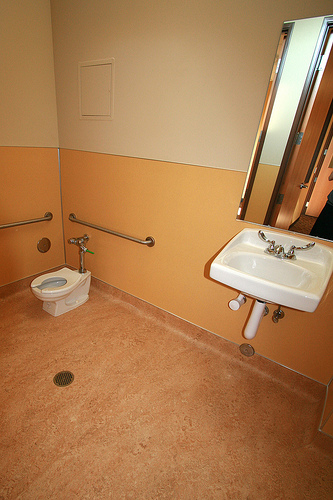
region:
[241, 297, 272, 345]
a white pipe under a sink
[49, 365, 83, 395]
a drain in a concrete floor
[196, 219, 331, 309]
a white bathroom sink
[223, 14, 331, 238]
a mirror over a sink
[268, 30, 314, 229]
a door reflected in a mirror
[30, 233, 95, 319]
a short white toilet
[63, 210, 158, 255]
metal railing around a toilet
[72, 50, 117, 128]
a small door in the wall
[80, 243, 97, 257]
a green flush lever on a toilet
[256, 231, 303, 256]
a faucet on a sink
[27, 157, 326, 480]
a clean public bathroom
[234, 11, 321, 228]
a shiny bathroom mirror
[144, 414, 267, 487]
the tan bathroom floor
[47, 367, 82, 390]
a drain in the floor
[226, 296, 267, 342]
white pipes under the sink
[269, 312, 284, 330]
water cut off valve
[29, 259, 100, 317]
a white bathroom toilet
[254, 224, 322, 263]
shiny silver faucet handles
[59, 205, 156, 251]
the handicap railing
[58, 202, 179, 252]
METAL BAR ON BATHROOM WALL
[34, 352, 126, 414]
DRAIN HOLE IN BATHROOM FLOOR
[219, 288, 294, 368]
PLUMBING PIPES TO THE BATHROOM SINK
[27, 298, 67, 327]
BROWN BATHROOM FLOORING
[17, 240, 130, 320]
WHITE TOILET IN A BATHROOM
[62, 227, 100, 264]
GREEN FLUSHING HANDLE ON TOILET PLUMBING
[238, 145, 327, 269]
MIRROR IN A BATHROOM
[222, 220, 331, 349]
WHITE SINK ATTACHED TO BATHROOM WALL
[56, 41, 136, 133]
SQUARE ACCESS PANEL IN BATHROOM WALL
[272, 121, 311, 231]
DOOR HINGES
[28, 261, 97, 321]
short white toilet fixture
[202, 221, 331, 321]
white porcelain sink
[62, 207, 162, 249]
metal silver safety bar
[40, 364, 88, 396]
brassy floor drain for water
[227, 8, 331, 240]
big mirror in front of sink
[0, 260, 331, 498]
burnt sienna colored linoleum flooring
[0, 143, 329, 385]
light orange coloured wainscotting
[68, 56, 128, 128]
small door in the wall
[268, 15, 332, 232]
reflection of a wooden door with a metal fram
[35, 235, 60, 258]
silver disk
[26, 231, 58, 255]
round silver orb on wall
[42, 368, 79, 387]
small gold grate on floor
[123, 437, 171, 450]
small brown stain on floor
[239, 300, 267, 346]
white pipe under sink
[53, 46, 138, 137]
square vent opening on wall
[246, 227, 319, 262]
silver faucets on white sink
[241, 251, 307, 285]
edge of white skin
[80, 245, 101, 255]
green handle flush on toilet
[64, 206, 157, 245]
large silver rail on wall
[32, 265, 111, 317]
white toilet on floor